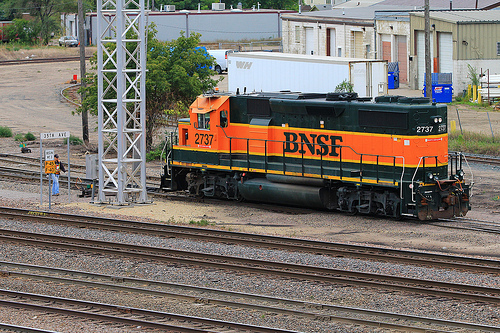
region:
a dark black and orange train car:
[163, 94, 467, 221]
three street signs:
[38, 130, 71, 201]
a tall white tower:
[89, 0, 149, 205]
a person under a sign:
[42, 138, 72, 193]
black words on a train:
[282, 129, 345, 160]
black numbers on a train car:
[188, 131, 215, 146]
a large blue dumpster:
[423, 70, 454, 100]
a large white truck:
[223, 49, 387, 103]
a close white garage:
[408, 20, 460, 90]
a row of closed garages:
[278, 20, 456, 92]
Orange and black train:
[157, 93, 470, 222]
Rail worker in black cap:
[47, 153, 68, 197]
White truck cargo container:
[227, 50, 387, 98]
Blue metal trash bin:
[422, 74, 452, 101]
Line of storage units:
[280, 14, 498, 91]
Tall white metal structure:
[96, 0, 146, 203]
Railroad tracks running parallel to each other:
[0, 206, 499, 331]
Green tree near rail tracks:
[76, 20, 218, 160]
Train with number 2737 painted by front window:
[161, 88, 471, 220]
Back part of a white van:
[196, 48, 230, 75]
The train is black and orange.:
[152, 73, 486, 258]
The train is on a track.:
[131, 75, 496, 278]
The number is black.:
[190, 127, 200, 148]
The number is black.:
[196, 130, 206, 146]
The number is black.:
[200, 127, 210, 147]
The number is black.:
[205, 131, 219, 145]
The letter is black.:
[280, 126, 300, 157]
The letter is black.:
[296, 122, 316, 159]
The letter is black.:
[314, 128, 330, 158]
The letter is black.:
[327, 131, 347, 166]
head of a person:
[46, 139, 63, 161]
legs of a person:
[46, 175, 66, 198]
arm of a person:
[59, 159, 69, 173]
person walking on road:
[42, 144, 71, 199]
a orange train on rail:
[128, 28, 493, 233]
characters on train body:
[260, 126, 356, 163]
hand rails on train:
[217, 126, 482, 213]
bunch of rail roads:
[63, 202, 415, 327]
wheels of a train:
[185, 158, 422, 224]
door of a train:
[172, 103, 194, 145]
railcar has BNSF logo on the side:
[280, 131, 346, 157]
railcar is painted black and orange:
[172, 91, 462, 206]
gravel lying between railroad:
[155, 237, 247, 253]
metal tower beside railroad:
[93, 3, 150, 202]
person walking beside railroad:
[45, 155, 69, 202]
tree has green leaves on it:
[155, 50, 194, 90]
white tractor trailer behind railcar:
[225, 52, 384, 92]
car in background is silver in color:
[56, 33, 79, 48]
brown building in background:
[407, 15, 499, 58]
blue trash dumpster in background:
[420, 72, 459, 100]